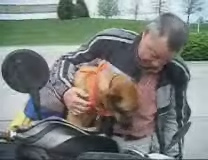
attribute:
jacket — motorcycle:
[48, 27, 189, 158]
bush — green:
[184, 35, 207, 58]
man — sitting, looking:
[123, 28, 199, 68]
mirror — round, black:
[1, 47, 50, 91]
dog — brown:
[7, 59, 141, 139]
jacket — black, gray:
[71, 23, 194, 123]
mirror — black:
[2, 42, 52, 119]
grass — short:
[0, 19, 207, 48]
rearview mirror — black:
[3, 47, 47, 127]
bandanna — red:
[77, 69, 115, 117]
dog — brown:
[24, 56, 139, 133]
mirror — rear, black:
[0, 45, 52, 94]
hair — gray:
[143, 13, 188, 52]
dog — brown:
[69, 53, 153, 148]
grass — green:
[35, 24, 71, 32]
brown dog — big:
[65, 58, 139, 131]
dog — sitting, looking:
[66, 57, 143, 133]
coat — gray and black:
[76, 27, 205, 127]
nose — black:
[101, 91, 143, 128]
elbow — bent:
[49, 45, 81, 76]